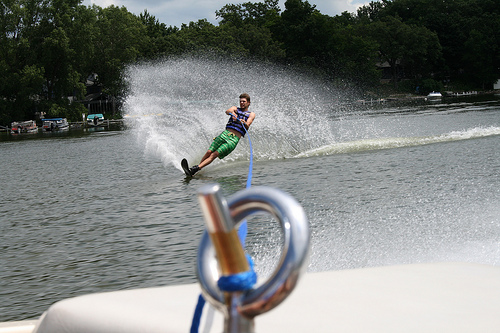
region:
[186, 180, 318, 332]
steel ring on a boat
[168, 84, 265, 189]
man on water skiis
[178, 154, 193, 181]
black colored water ski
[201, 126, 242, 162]
man's green stiped swim trunks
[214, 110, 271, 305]
blue colored rope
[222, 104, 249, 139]
man's blue colored vest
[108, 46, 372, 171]
splash in water from a water skiier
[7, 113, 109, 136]
three boats at a boat dock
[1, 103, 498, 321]
brown body of water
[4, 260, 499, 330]
white end of a boat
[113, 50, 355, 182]
a person is water skiing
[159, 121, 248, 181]
the man is slalom water skiing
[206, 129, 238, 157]
the man has green shorts on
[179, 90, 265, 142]
the man has a ski vest on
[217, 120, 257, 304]
the ski rope is blue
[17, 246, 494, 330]
the transom of the boat is white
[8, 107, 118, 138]
boats are moored lakeside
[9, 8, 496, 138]
trees are behind the skier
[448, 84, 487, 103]
a dock has white pilings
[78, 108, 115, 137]
the boat is on a boat lift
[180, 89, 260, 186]
A man waterskiing.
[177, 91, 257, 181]
Person in green swim trunks.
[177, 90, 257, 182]
Person wearing a life vest.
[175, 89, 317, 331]
Man waterskiing with a blue cable.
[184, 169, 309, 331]
Metal piece used to tow waterskiier.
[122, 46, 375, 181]
Spray from skis cutting through the water.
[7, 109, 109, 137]
Three boats docked by the shore.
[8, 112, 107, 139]
Three boats.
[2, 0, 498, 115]
Trees on the shore.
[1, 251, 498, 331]
Back of a speed boat.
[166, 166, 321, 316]
circular metal ring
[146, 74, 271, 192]
man in green shorts water skiing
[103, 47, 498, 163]
water sprays in to the air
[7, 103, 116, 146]
group of three docked boats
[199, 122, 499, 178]
wake behind the water skier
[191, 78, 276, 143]
the man is wearing a blue life jacket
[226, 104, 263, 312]
blue rope attached to the boat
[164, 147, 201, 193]
black water ski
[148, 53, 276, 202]
water skier using one ski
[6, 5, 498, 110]
row of green leafy trees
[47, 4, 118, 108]
Group of tall, lush, green trees.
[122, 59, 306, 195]
Man watersking with purple lifevest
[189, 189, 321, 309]
Silver circle and rod with blue string tied around it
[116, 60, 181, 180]
high water spray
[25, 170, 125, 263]
calm part of lake with gray looking water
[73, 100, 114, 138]
boat docked on pier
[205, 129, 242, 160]
green swim shorts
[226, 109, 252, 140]
purple life vest with black buckles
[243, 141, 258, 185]
blue rope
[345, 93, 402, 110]
dark colored dock